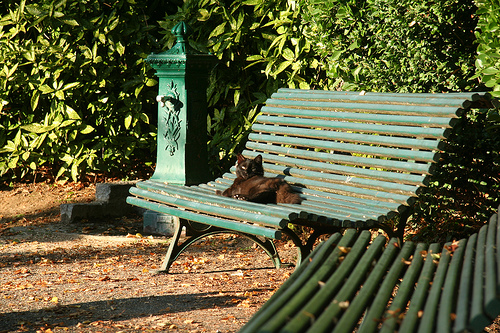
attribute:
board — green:
[121, 195, 280, 242]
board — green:
[248, 128, 440, 162]